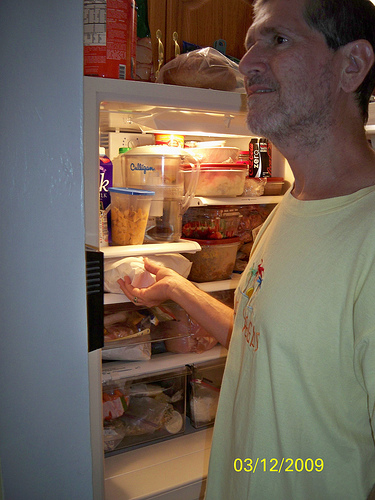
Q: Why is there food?
A: To eat.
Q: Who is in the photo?
A: A man.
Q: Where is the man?
A: In the kitchen.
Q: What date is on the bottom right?
A: 03/12/2009.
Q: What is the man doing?
A: Grabbing something.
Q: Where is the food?
A: In the fridge.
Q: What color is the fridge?
A: White.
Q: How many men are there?
A: One.